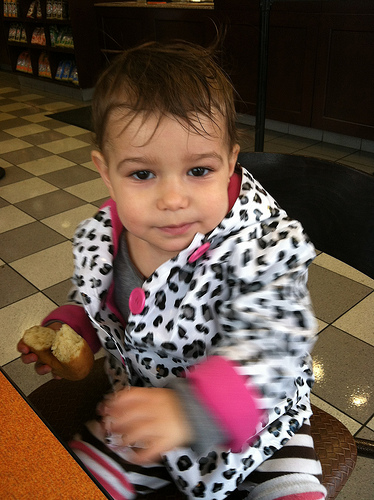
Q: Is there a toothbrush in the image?
A: No, there are no toothbrushes.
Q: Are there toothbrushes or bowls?
A: No, there are no toothbrushes or bowls.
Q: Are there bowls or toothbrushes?
A: No, there are no toothbrushes or bowls.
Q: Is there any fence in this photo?
A: No, there are no fences.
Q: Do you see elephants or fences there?
A: No, there are no fences or elephants.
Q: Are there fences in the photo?
A: No, there are no fences.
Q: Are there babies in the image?
A: Yes, there is a baby.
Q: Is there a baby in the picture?
A: Yes, there is a baby.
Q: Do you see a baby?
A: Yes, there is a baby.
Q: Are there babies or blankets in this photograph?
A: Yes, there is a baby.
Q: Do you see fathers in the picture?
A: No, there are no fathers.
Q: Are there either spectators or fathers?
A: No, there are no fathers or spectators.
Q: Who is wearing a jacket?
A: The baby is wearing a jacket.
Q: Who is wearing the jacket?
A: The baby is wearing a jacket.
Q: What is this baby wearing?
A: The baby is wearing a jacket.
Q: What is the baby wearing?
A: The baby is wearing a jacket.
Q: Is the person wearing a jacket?
A: Yes, the baby is wearing a jacket.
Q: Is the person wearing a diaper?
A: No, the baby is wearing a jacket.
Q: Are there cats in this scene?
A: No, there are no cats.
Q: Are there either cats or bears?
A: No, there are no cats or bears.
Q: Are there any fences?
A: No, there are no fences.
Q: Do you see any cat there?
A: No, there are no cats.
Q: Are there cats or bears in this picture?
A: No, there are no cats or bears.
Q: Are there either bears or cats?
A: No, there are no cats or bears.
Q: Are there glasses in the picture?
A: No, there are no glasses.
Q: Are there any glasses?
A: No, there are no glasses.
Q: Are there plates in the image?
A: No, there are no plates.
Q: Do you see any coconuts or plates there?
A: No, there are no plates or coconuts.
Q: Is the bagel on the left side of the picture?
A: Yes, the bagel is on the left of the image.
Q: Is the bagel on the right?
A: No, the bagel is on the left of the image.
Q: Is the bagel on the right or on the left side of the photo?
A: The bagel is on the left of the image.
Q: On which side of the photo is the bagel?
A: The bagel is on the left of the image.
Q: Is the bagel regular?
A: Yes, the bagel is regular.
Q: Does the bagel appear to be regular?
A: Yes, the bagel is regular.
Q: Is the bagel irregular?
A: No, the bagel is regular.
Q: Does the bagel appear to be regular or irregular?
A: The bagel is regular.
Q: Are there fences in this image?
A: No, there are no fences.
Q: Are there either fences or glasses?
A: No, there are no fences or glasses.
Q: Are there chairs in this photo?
A: Yes, there is a chair.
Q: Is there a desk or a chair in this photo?
A: Yes, there is a chair.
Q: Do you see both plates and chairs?
A: No, there is a chair but no plates.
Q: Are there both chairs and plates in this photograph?
A: No, there is a chair but no plates.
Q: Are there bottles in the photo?
A: No, there are no bottles.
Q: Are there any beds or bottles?
A: No, there are no bottles or beds.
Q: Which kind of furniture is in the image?
A: The furniture is a chair.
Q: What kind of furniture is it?
A: The piece of furniture is a chair.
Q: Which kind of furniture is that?
A: This is a chair.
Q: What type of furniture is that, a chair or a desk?
A: This is a chair.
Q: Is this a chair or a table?
A: This is a chair.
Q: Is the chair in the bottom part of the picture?
A: Yes, the chair is in the bottom of the image.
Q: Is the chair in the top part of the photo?
A: No, the chair is in the bottom of the image.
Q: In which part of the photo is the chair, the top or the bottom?
A: The chair is in the bottom of the image.